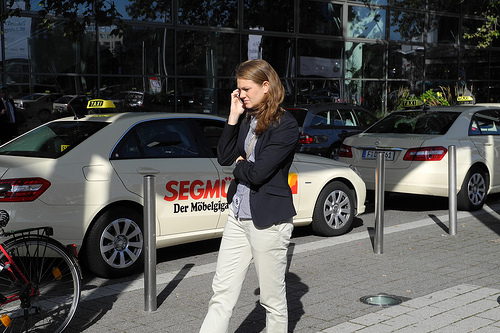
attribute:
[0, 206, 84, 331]
bicycle — black, metal, red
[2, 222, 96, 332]
bike — red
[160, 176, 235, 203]
text — red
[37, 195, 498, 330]
sidewalk — grey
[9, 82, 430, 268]
taxi — parked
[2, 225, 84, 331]
bike — in front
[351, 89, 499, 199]
taxi cab — white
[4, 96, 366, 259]
taxi cab — white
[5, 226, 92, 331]
wheel — black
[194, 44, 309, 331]
woman — standing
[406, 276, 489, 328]
sidewalk — grey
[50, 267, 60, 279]
reflector — yellow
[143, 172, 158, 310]
pole — metal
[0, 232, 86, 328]
tire — black, silver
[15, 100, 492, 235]
cars — white, metal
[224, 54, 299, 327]
woman — standing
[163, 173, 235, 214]
company name — red, black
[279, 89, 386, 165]
car — dark, gray, metal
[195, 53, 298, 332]
woman — talking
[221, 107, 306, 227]
jacket — blue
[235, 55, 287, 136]
hair — brown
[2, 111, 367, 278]
car — white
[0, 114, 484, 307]
street — full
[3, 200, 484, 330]
sidewalk — concrete, grey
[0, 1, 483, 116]
building — dark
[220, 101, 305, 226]
blazer — blue